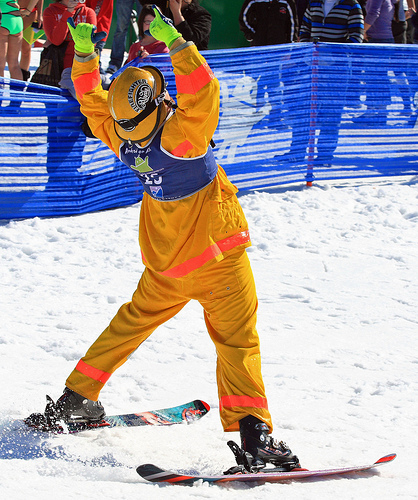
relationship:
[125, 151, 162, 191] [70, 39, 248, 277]
number on vest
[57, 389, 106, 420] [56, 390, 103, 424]
strap on boot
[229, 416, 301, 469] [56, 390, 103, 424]
strap on boot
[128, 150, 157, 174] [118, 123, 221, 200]
robot on vest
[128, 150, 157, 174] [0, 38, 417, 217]
robot on fence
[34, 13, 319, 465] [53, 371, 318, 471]
skier wearing boot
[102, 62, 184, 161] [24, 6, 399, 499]
helmet on skier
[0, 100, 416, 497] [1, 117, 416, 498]
white snow on ground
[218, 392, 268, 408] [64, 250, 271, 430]
reflective material on pants